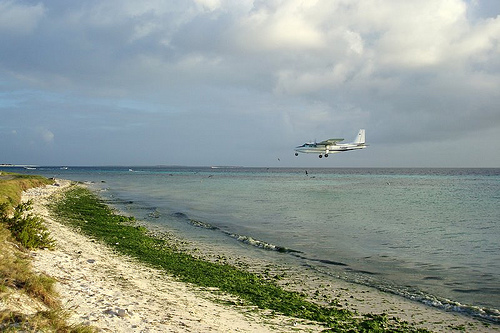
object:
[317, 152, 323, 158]
wheels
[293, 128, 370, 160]
plane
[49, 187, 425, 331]
seaweed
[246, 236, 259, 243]
cap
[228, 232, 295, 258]
wave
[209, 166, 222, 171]
boat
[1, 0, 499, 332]
background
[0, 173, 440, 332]
land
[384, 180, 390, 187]
buoy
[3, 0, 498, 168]
sky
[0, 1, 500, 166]
clouds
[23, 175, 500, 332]
sand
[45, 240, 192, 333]
tracks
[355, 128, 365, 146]
tail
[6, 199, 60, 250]
plants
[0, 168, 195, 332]
hill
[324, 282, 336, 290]
rocks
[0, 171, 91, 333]
grass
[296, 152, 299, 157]
wheel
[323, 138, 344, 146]
wing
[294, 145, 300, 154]
nose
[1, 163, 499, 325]
sea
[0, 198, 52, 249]
bush